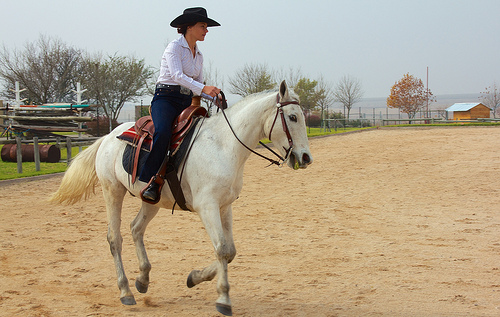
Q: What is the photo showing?
A: It is showing a field.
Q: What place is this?
A: It is a field.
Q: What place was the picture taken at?
A: It was taken at the field.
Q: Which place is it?
A: It is a field.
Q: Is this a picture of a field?
A: Yes, it is showing a field.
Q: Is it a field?
A: Yes, it is a field.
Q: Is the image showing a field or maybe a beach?
A: It is showing a field.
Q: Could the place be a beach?
A: No, it is a field.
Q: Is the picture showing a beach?
A: No, the picture is showing a field.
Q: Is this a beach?
A: No, it is a field.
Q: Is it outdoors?
A: Yes, it is outdoors.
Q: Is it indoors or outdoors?
A: It is outdoors.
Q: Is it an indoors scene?
A: No, it is outdoors.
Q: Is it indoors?
A: No, it is outdoors.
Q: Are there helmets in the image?
A: No, there are no helmets.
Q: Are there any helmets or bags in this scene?
A: No, there are no helmets or bags.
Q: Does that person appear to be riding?
A: Yes, the person is riding.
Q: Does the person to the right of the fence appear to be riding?
A: Yes, the person is riding.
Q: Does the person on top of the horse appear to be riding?
A: Yes, the person is riding.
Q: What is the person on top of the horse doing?
A: The person is riding.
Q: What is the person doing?
A: The person is riding.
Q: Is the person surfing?
A: No, the person is riding.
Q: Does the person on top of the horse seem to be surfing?
A: No, the person is riding.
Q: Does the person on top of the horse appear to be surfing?
A: No, the person is riding.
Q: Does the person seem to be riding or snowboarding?
A: The person is riding.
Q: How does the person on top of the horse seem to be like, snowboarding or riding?
A: The person is riding.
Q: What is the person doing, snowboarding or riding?
A: The person is riding.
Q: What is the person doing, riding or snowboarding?
A: The person is riding.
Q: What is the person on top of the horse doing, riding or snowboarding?
A: The person is riding.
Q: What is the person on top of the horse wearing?
A: The person is wearing jeans.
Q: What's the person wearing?
A: The person is wearing jeans.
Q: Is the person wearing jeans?
A: Yes, the person is wearing jeans.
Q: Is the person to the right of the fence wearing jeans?
A: Yes, the person is wearing jeans.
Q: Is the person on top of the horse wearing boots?
A: No, the person is wearing jeans.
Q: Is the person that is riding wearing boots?
A: No, the person is wearing jeans.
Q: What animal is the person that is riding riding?
A: The person is riding a horse.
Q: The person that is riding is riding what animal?
A: The person is riding a horse.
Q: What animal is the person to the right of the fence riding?
A: The person is riding a horse.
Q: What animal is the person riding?
A: The person is riding a horse.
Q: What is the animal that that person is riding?
A: The animal is a horse.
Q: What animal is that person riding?
A: The person is riding a horse.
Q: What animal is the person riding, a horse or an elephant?
A: The person is riding a horse.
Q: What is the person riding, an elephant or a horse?
A: The person is riding a horse.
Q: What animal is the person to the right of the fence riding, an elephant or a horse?
A: The person is riding a horse.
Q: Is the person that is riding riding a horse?
A: Yes, the person is riding a horse.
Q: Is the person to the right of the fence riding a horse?
A: Yes, the person is riding a horse.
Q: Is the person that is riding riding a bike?
A: No, the person is riding a horse.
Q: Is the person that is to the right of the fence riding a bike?
A: No, the person is riding a horse.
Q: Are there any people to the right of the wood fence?
A: Yes, there is a person to the right of the fence.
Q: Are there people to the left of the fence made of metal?
A: No, the person is to the right of the fence.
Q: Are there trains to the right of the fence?
A: No, there is a person to the right of the fence.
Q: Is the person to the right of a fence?
A: Yes, the person is to the right of a fence.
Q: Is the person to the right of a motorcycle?
A: No, the person is to the right of a fence.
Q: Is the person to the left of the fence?
A: No, the person is to the right of the fence.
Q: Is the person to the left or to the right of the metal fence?
A: The person is to the right of the fence.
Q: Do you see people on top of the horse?
A: Yes, there is a person on top of the horse.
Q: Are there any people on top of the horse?
A: Yes, there is a person on top of the horse.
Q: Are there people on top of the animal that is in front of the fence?
A: Yes, there is a person on top of the horse.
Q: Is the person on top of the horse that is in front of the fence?
A: Yes, the person is on top of the horse.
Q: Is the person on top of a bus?
A: No, the person is on top of the horse.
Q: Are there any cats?
A: No, there are no cats.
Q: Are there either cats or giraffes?
A: No, there are no cats or giraffes.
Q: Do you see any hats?
A: Yes, there is a hat.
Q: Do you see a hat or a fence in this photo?
A: Yes, there is a hat.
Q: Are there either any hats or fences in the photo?
A: Yes, there is a hat.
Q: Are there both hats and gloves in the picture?
A: No, there is a hat but no gloves.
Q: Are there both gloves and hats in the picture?
A: No, there is a hat but no gloves.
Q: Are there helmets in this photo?
A: No, there are no helmets.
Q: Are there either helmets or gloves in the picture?
A: No, there are no helmets or gloves.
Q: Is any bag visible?
A: No, there are no bags.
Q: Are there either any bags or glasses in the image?
A: No, there are no bags or glasses.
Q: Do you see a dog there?
A: No, there are no dogs.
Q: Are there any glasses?
A: No, there are no glasses.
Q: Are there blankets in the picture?
A: Yes, there is a blanket.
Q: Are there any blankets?
A: Yes, there is a blanket.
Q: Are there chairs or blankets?
A: Yes, there is a blanket.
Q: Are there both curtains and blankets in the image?
A: No, there is a blanket but no curtains.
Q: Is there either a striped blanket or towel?
A: Yes, there is a striped blanket.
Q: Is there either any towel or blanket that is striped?
A: Yes, the blanket is striped.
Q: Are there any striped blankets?
A: Yes, there is a striped blanket.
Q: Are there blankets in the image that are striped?
A: Yes, there is a blanket that is striped.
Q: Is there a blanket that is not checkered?
A: Yes, there is a striped blanket.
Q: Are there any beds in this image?
A: No, there are no beds.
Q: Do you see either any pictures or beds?
A: No, there are no beds or pictures.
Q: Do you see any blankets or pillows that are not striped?
A: No, there is a blanket but it is striped.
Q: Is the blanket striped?
A: Yes, the blanket is striped.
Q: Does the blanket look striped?
A: Yes, the blanket is striped.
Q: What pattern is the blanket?
A: The blanket is striped.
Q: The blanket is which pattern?
A: The blanket is striped.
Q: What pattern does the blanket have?
A: The blanket has striped pattern.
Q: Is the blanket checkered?
A: No, the blanket is striped.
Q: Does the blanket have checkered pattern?
A: No, the blanket is striped.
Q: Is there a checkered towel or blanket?
A: No, there is a blanket but it is striped.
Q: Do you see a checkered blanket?
A: No, there is a blanket but it is striped.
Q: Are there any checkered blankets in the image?
A: No, there is a blanket but it is striped.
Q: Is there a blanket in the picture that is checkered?
A: No, there is a blanket but it is striped.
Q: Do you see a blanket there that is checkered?
A: No, there is a blanket but it is striped.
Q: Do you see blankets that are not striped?
A: No, there is a blanket but it is striped.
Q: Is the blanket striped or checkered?
A: The blanket is striped.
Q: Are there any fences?
A: Yes, there is a fence.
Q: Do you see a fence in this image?
A: Yes, there is a fence.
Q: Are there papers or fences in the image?
A: Yes, there is a fence.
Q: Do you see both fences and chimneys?
A: No, there is a fence but no chimneys.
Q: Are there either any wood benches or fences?
A: Yes, there is a wood fence.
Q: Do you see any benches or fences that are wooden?
A: Yes, the fence is wooden.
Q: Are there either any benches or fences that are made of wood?
A: Yes, the fence is made of wood.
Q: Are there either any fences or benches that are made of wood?
A: Yes, the fence is made of wood.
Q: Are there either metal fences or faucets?
A: Yes, there is a metal fence.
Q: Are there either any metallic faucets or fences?
A: Yes, there is a metal fence.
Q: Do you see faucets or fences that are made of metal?
A: Yes, the fence is made of metal.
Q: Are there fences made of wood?
A: Yes, there is a fence that is made of wood.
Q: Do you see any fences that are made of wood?
A: Yes, there is a fence that is made of wood.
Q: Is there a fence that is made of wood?
A: Yes, there is a fence that is made of wood.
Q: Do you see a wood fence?
A: Yes, there is a fence that is made of wood.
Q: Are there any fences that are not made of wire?
A: Yes, there is a fence that is made of wood.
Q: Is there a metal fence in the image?
A: Yes, there is a metal fence.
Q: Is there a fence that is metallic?
A: Yes, there is a fence that is metallic.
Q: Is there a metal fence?
A: Yes, there is a fence that is made of metal.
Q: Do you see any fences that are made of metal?
A: Yes, there is a fence that is made of metal.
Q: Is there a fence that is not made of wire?
A: Yes, there is a fence that is made of metal.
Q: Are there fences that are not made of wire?
A: Yes, there is a fence that is made of metal.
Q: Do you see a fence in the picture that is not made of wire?
A: Yes, there is a fence that is made of metal.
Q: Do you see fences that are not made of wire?
A: Yes, there is a fence that is made of metal.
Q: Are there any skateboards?
A: No, there are no skateboards.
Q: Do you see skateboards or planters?
A: No, there are no skateboards or planters.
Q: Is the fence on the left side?
A: Yes, the fence is on the left of the image.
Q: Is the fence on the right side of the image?
A: No, the fence is on the left of the image.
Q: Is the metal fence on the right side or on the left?
A: The fence is on the left of the image.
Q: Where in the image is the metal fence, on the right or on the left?
A: The fence is on the left of the image.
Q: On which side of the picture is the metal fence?
A: The fence is on the left of the image.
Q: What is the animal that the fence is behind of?
A: The animal is a horse.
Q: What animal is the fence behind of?
A: The fence is behind the horse.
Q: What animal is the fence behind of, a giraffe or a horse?
A: The fence is behind a horse.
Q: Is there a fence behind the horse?
A: Yes, there is a fence behind the horse.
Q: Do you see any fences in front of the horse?
A: No, the fence is behind the horse.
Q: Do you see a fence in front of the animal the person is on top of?
A: No, the fence is behind the horse.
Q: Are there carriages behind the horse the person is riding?
A: No, there is a fence behind the horse.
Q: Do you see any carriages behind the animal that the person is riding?
A: No, there is a fence behind the horse.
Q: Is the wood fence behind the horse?
A: Yes, the fence is behind the horse.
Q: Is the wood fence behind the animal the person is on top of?
A: Yes, the fence is behind the horse.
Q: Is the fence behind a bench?
A: No, the fence is behind the horse.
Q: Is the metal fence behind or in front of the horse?
A: The fence is behind the horse.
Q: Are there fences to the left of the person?
A: Yes, there is a fence to the left of the person.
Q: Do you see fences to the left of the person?
A: Yes, there is a fence to the left of the person.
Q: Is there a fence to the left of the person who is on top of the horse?
A: Yes, there is a fence to the left of the person.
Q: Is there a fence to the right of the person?
A: No, the fence is to the left of the person.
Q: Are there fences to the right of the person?
A: No, the fence is to the left of the person.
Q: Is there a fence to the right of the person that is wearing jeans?
A: No, the fence is to the left of the person.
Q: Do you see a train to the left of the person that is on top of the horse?
A: No, there is a fence to the left of the person.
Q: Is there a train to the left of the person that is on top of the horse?
A: No, there is a fence to the left of the person.